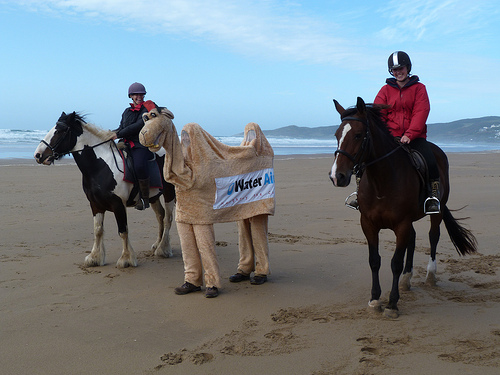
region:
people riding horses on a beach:
[35, 42, 482, 310]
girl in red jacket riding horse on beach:
[325, 42, 457, 202]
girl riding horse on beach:
[115, 64, 161, 135]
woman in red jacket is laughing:
[369, 47, 424, 99]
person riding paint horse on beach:
[25, 104, 127, 269]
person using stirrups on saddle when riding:
[411, 176, 459, 248]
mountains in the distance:
[280, 94, 320, 172]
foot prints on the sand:
[129, 291, 462, 358]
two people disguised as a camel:
[135, 108, 305, 287]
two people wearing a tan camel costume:
[137, 108, 279, 315]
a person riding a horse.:
[321, 38, 475, 313]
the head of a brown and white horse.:
[321, 96, 385, 187]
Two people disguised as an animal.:
[132, 108, 281, 288]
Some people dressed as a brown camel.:
[140, 108, 285, 284]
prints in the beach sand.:
[138, 306, 402, 367]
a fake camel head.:
[137, 103, 166, 167]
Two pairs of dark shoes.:
[162, 264, 289, 299]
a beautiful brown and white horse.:
[20, 110, 141, 265]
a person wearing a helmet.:
[375, 48, 423, 87]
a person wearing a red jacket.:
[363, 36, 438, 157]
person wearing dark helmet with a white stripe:
[383, 50, 414, 70]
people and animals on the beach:
[10, 0, 490, 372]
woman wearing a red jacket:
[360, 62, 432, 145]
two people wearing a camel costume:
[132, 100, 289, 306]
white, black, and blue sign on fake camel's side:
[208, 163, 280, 210]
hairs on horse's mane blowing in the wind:
[47, 103, 99, 135]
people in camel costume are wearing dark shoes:
[169, 261, 276, 303]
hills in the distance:
[229, 114, 499, 141]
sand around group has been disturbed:
[70, 222, 498, 372]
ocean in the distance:
[0, 123, 481, 158]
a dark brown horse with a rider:
[325, 97, 488, 336]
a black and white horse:
[31, 110, 173, 272]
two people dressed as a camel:
[138, 107, 280, 305]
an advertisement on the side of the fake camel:
[212, 167, 277, 205]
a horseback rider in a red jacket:
[371, 49, 431, 145]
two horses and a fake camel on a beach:
[32, 57, 476, 316]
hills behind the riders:
[252, 115, 499, 141]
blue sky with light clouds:
[3, 2, 369, 103]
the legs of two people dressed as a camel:
[171, 220, 276, 300]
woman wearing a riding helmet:
[373, 50, 430, 147]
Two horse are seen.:
[23, 82, 456, 330]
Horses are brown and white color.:
[46, 106, 434, 274]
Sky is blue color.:
[37, 23, 192, 78]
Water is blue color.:
[6, 133, 34, 147]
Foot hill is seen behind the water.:
[265, 102, 499, 159]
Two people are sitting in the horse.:
[111, 78, 438, 154]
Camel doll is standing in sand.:
[133, 96, 285, 299]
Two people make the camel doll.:
[152, 168, 278, 308]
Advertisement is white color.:
[213, 167, 285, 209]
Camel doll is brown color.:
[143, 111, 293, 287]